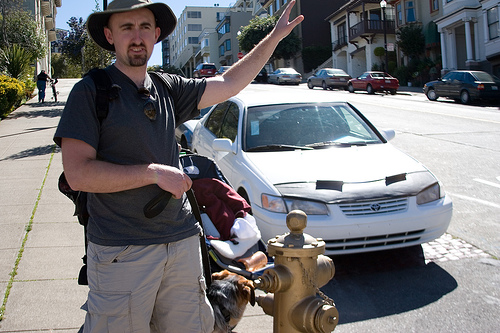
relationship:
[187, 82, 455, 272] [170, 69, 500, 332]
car on street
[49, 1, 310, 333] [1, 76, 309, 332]
man on sidewalk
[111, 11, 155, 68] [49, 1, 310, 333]
face of man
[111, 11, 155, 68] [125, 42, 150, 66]
face with goatee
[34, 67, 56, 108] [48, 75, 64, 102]
man pushing bike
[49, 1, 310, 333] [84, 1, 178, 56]
man wearing hat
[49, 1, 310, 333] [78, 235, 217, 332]
man wearing pants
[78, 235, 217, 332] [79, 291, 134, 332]
pants have pocket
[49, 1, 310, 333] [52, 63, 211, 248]
man wearing t-shirt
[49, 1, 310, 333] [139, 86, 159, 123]
man has sunglasses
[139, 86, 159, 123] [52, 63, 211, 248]
sunglasses in t-shirt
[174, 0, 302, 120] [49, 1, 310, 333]
arm of man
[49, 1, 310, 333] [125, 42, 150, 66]
man has goatee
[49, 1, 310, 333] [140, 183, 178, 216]
man hold leash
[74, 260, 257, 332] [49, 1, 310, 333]
dog next to man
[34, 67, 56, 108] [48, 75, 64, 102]
man with bike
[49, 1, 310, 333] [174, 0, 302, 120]
man with arm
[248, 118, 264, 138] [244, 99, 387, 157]
sticker in window